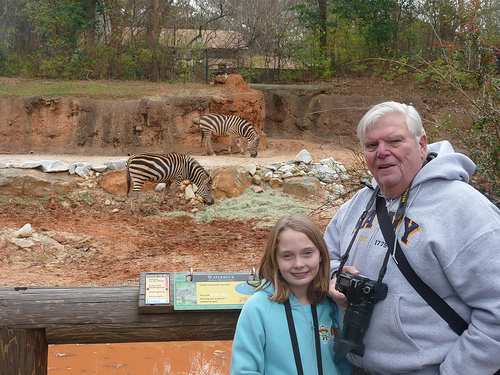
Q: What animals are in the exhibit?
A: Zebras.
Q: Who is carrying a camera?
A: An older man in a grey hoodie.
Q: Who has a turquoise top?
A: A girl, standing beside an older man.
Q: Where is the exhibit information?
A: On a log, beside the girl.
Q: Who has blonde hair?
A: A young girl.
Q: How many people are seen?
A: Two.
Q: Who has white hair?
A: An older gentleman, in a hoodie.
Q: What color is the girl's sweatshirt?
A: Blue.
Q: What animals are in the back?
A: Zebras.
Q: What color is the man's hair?
A: White.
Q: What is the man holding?
A: A camera.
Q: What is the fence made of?
A: Wood.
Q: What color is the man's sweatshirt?
A: Gray.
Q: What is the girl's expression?
A: Smiling.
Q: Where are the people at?
A: The zoo.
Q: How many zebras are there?
A: 2.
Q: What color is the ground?
A: Red.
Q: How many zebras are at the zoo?
A: Two.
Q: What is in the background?
A: Bare trees.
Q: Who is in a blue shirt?
A: A young girl.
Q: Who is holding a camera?
A: A heavy set man.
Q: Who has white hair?
A: A man.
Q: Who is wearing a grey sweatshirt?
A: A man.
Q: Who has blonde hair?
A: A girl.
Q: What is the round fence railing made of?
A: Wood.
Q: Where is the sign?
A: On the fence railing.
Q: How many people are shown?
A: 2.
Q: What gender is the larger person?
A: Male.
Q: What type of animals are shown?
A: Zebras.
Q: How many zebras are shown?
A: 2.